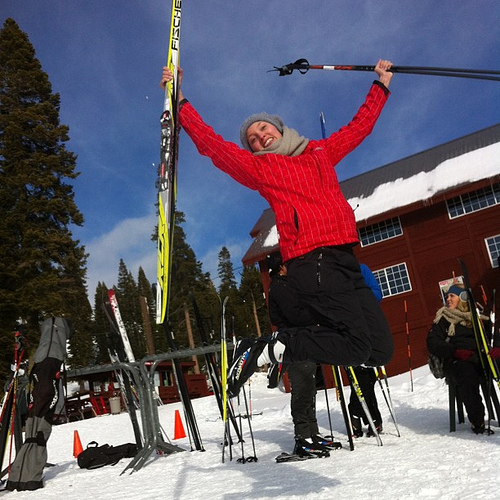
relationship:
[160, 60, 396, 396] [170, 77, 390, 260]
person wearing coat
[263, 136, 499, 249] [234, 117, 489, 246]
snow on top of roof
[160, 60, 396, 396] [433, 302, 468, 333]
person wearing scarf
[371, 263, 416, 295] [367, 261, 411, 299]
window has cross bars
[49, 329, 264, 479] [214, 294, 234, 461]
rack holding skis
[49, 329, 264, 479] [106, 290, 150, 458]
rack holding skis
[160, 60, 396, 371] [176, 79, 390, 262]
person wearing a coat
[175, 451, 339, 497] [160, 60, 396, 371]
shadow of person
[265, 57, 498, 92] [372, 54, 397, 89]
ski sticks on left hand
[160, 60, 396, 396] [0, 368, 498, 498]
person jumping in snow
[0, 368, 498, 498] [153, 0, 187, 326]
snow holding skis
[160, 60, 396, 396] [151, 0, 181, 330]
person holding skis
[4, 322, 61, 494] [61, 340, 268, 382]
skis lying against rail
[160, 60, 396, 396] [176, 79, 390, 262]
person wearing a coat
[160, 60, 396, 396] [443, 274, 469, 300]
person with a headband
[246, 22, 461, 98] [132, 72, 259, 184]
stick in hand.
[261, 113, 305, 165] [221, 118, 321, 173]
scarf around neck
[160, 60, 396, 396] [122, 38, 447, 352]
person jumping in air